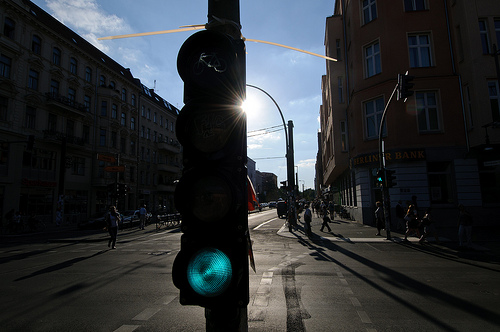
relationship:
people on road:
[90, 193, 437, 265] [0, 164, 466, 328]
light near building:
[170, 16, 270, 331] [1, 5, 204, 250]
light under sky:
[170, 16, 270, 331] [39, 2, 357, 189]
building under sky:
[1, 5, 204, 250] [39, 2, 357, 189]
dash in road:
[255, 213, 293, 247] [113, 179, 394, 326]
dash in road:
[242, 200, 292, 241] [90, 159, 386, 329]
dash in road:
[261, 200, 302, 276] [101, 146, 382, 327]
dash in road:
[244, 193, 293, 251] [99, 142, 339, 325]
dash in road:
[248, 206, 275, 242] [128, 155, 377, 327]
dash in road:
[244, 186, 296, 247] [93, 171, 349, 321]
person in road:
[106, 205, 122, 248] [0, 202, 494, 327]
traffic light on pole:
[173, 228, 258, 311] [170, 11, 273, 307]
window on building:
[362, 41, 383, 78] [301, 15, 471, 218]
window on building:
[362, 41, 383, 78] [317, 0, 462, 229]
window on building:
[362, 41, 383, 78] [317, 24, 469, 264]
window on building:
[362, 41, 383, 78] [317, 2, 493, 223]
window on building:
[362, 41, 383, 78] [319, 2, 495, 243]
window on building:
[348, 44, 397, 85] [317, 13, 484, 243]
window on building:
[362, 41, 383, 78] [308, 13, 466, 231]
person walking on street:
[95, 188, 131, 251] [48, 153, 458, 327]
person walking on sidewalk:
[288, 188, 322, 237] [270, 168, 479, 329]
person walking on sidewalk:
[310, 197, 344, 247] [266, 155, 482, 327]